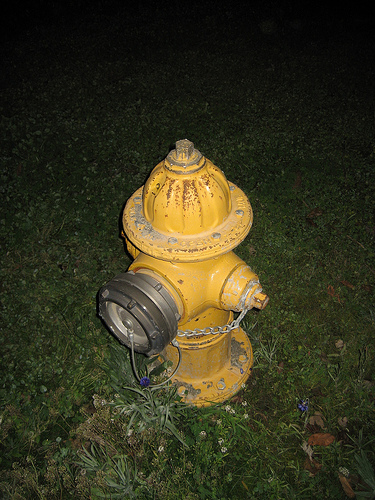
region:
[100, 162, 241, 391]
a yellow water pipe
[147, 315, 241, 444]
a yellow water pipe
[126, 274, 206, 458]
a yellow water pipe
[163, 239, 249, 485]
a yellow water pipe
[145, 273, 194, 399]
a yellow water pipe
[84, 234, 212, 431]
A yellow water pipe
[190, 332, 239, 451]
A yellow water pipe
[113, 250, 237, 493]
A yellow water pipe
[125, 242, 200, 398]
A yellow water pipe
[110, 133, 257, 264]
Top cover on a fire hydrant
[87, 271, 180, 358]
Security type cover on a fire hydrant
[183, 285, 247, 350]
Retaining chains for fire hydrant covers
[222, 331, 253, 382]
Chips in the paint on the fire hydrant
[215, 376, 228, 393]
Bolt securing fire hydrant to pipe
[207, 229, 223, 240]
Bolt securing cover of fire hydrant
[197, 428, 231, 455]
Clover flowers in the grass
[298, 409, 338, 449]
Fallen leaves in the grass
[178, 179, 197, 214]
Rust forming on the fire hydrant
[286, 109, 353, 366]
Large grassy field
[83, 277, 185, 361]
silver part of hydrant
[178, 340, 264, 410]
base of the hydrant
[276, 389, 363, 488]
leaves on the ground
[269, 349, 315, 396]
grass next to hydrant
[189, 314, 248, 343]
chain on the hydrant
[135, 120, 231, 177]
top of the hydrant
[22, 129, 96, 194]
dark grass in the background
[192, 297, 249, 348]
silver chain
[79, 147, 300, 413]
one fire hydrant on the grass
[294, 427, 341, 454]
one brown leaf in the green grass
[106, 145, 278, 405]
The fire hydrant is yellow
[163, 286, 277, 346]
The fire hydrant has a chain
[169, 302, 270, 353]
The chain is silver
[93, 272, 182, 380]
One side of the fire hydrant is grey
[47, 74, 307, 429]
The fire hydrant is in grass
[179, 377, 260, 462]
Small white flowers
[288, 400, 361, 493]
There are brown leaves in the grass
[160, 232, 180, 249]
Silver bolts on top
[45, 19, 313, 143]
It's night time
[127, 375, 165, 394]
Small purple flower next to the fire hydrant